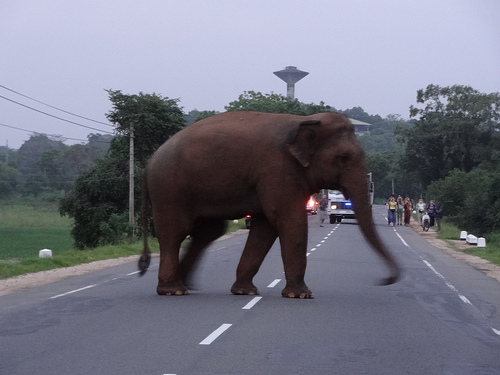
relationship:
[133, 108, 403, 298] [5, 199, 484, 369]
elephant walking across street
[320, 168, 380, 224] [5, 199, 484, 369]
truck on street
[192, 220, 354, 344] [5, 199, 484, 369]
lines on street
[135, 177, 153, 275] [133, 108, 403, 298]
tail of elephant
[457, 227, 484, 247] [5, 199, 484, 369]
objects of street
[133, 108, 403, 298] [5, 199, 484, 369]
elephant on street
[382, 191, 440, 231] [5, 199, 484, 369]
people on street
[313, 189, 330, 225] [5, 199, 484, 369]
man in street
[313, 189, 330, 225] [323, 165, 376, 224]
man next to rv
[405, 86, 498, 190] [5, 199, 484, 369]
tree on side of street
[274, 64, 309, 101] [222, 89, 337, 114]
building over tops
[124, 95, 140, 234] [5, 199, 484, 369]
pole on side of street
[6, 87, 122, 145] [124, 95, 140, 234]
lines on side of pole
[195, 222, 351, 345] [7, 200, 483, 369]
stripes on pavement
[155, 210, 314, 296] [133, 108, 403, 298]
legs of elephant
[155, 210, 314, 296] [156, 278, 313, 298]
legs with feet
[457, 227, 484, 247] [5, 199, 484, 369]
objects on street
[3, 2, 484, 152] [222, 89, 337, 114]
sky over tops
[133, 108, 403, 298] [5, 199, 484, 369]
elephant crossing street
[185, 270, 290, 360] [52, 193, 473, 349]
lines in street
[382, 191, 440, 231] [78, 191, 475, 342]
people walking on street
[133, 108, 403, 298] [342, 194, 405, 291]
elephant has trunk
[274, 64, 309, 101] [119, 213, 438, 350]
building on street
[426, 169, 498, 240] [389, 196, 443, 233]
tree next to people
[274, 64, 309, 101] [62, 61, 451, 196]
building in background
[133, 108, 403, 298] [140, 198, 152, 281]
elephant has tail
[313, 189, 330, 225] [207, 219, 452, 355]
man in street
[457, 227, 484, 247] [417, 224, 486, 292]
objects on side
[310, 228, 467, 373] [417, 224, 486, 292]
road has side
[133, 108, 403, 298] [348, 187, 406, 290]
elephant has trunk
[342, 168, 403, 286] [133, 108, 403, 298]
truck of elephant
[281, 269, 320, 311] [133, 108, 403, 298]
foot of elephant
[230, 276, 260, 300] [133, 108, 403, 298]
foot of elephant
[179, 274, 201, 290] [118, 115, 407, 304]
foot of elephant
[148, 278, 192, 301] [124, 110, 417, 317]
foot of elephant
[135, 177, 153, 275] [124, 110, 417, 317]
tail of elephant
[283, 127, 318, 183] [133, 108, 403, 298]
ear of elephant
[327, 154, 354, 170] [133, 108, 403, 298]
eye of elephant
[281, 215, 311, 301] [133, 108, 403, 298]
leg of elephant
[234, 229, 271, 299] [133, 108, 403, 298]
leg of elephant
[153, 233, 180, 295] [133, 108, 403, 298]
leg of elephant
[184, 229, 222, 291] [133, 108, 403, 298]
leg of elephant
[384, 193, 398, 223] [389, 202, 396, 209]
person wearing shirt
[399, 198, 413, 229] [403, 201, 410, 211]
person wearing shirt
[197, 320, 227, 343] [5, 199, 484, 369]
line on street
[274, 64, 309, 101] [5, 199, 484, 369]
building on street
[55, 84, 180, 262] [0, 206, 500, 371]
tree on side of road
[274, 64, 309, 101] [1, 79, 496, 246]
building poking on top of trees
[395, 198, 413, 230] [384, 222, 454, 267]
person on road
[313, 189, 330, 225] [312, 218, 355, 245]
man on street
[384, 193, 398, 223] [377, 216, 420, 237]
person on street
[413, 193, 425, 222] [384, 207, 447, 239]
person on street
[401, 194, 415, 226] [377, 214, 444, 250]
person on street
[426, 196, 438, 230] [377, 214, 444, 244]
person on street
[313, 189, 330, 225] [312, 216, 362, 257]
man on street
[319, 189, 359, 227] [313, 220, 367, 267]
car on street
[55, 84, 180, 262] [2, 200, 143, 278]
tree on field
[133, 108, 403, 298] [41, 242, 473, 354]
elephant on street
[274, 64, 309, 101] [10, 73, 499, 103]
building on background